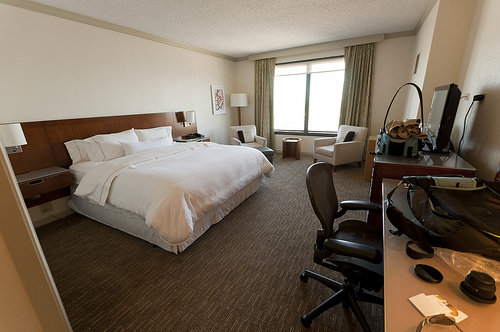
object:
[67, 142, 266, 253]
bed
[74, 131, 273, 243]
comforter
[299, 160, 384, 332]
chair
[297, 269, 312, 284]
wheels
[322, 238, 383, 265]
arm rests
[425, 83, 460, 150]
tv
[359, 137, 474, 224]
dresser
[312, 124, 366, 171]
chair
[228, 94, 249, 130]
lamp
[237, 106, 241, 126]
pole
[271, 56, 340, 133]
window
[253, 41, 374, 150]
drapes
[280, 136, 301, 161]
table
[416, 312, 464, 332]
glasses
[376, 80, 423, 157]
bag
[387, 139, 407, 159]
pockets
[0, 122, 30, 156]
lamp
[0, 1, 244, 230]
wall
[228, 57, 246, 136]
corner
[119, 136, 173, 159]
pillows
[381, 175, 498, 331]
desk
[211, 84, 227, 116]
picture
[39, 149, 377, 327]
carpet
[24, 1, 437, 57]
ceiling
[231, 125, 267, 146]
chair